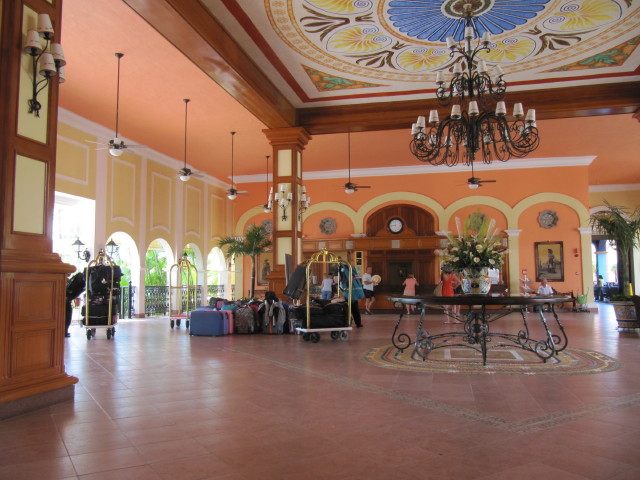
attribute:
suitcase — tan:
[221, 300, 261, 339]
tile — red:
[432, 379, 476, 405]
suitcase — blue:
[182, 301, 228, 339]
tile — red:
[381, 378, 404, 407]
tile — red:
[543, 383, 567, 398]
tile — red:
[339, 349, 359, 360]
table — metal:
[368, 287, 601, 359]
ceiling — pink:
[69, 23, 272, 182]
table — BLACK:
[385, 282, 581, 362]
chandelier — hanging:
[384, 0, 558, 189]